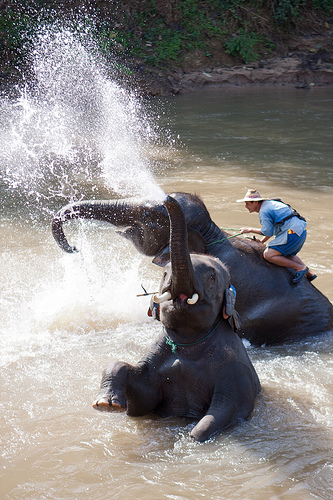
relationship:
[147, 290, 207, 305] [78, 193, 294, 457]
tusks are on elephant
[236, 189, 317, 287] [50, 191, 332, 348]
man riding elephant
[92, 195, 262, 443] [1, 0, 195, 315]
elephant shooting water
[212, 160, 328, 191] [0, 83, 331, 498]
ripples are in water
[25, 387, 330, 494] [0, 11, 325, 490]
ripples are in water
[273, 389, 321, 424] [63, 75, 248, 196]
ripples are in water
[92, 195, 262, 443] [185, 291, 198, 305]
elephant has tusk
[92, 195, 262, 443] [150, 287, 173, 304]
elephant has tusk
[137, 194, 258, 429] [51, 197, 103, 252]
elephant has trunk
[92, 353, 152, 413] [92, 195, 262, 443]
leg on elephant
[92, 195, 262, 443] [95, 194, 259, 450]
elephant squirting water out nose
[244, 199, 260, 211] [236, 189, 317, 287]
head on man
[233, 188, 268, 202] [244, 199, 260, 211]
hat on head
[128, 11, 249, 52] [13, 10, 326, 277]
plant on side of terrain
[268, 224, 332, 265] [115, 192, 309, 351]
shorts on elephant